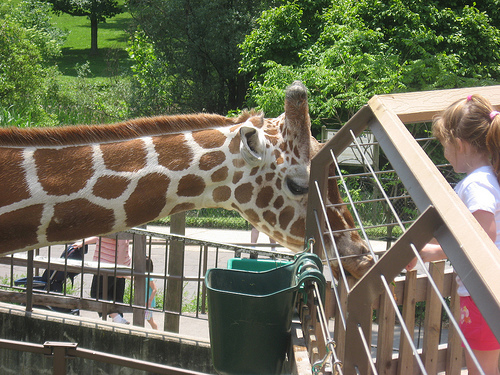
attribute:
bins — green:
[205, 252, 323, 374]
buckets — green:
[201, 246, 283, 373]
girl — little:
[431, 94, 498, 374]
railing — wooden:
[310, 83, 498, 354]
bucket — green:
[208, 250, 335, 374]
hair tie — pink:
[483, 106, 498, 121]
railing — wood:
[226, 64, 486, 374]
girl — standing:
[409, 79, 496, 366]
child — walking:
[433, 96, 497, 368]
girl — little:
[409, 113, 497, 248]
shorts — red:
[453, 294, 499, 354]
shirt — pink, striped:
[91, 234, 130, 273]